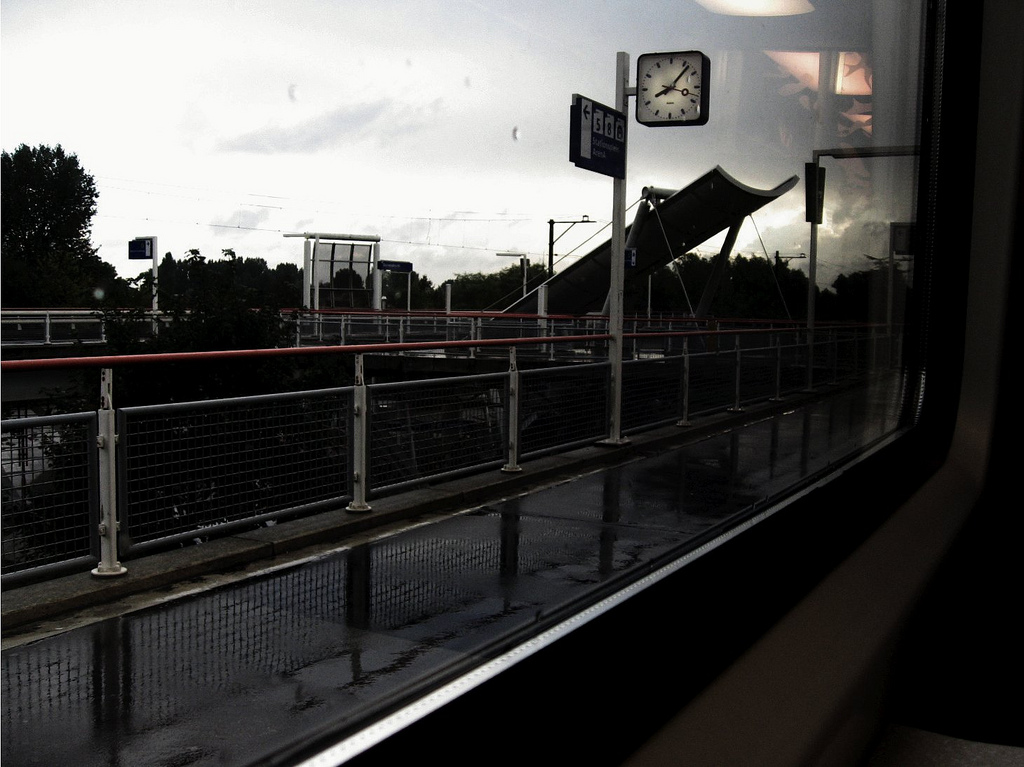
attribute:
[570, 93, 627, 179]
sign — white, black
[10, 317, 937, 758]
fence — metal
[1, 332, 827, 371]
railing — red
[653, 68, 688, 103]
hands — black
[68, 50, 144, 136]
sky — grey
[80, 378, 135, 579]
pole — white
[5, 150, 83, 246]
bush — green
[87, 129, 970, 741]
scene — daytime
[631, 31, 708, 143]
clock — white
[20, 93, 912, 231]
sky — gray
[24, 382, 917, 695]
fence — gray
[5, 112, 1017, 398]
trees — some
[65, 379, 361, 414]
rail — metal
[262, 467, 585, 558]
rail — metal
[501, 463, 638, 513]
rail — metal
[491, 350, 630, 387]
rail — metal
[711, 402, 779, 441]
rail — metal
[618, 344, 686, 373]
rail — metal